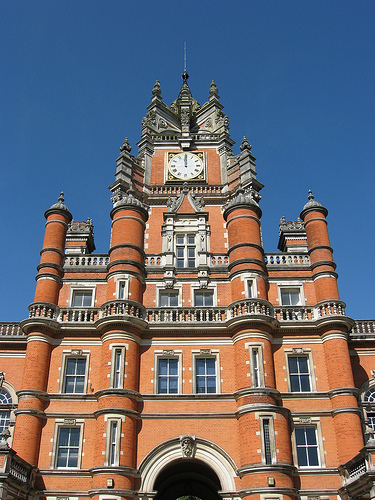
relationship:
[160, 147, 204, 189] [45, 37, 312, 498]
clock on tower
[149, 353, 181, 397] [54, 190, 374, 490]
window on building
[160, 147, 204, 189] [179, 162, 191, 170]
clock with time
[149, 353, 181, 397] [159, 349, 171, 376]
window has four panes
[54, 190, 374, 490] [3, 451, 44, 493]
building has railing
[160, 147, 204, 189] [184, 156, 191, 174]
clock has hand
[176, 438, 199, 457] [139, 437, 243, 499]
statue on archway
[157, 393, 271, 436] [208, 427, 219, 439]
wall has brick